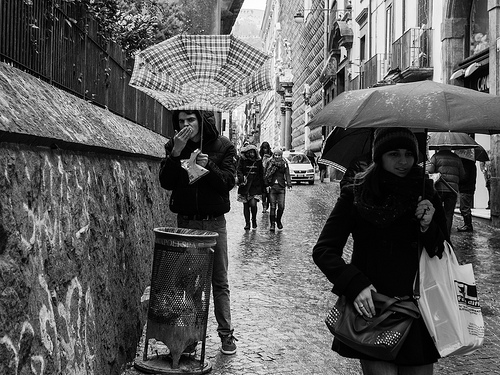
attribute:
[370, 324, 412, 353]
pattern — decorative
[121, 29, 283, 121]
umbrella — plaid 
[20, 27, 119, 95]
fence — metal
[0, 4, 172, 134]
fencing — iron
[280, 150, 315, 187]
car — small, parked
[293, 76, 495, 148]
umbrellas — held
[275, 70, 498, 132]
umbrella — wet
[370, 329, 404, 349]
studs — metal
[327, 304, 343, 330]
studs — metal